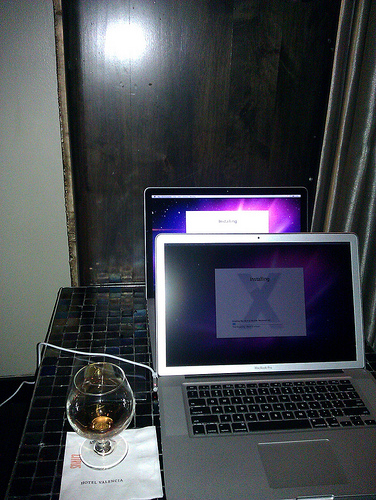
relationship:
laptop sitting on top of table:
[151, 234, 374, 497] [4, 283, 362, 498]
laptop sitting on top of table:
[143, 184, 309, 367] [4, 283, 362, 498]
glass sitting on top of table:
[65, 361, 137, 470] [4, 283, 362, 498]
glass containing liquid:
[65, 361, 137, 470] [67, 377, 136, 436]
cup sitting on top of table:
[65, 359, 137, 475] [4, 283, 362, 498]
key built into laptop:
[191, 423, 206, 435] [151, 234, 374, 497]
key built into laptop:
[188, 404, 213, 414] [151, 234, 374, 497]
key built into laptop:
[210, 386, 222, 397] [151, 234, 374, 497]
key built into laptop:
[190, 406, 212, 415] [151, 234, 374, 497]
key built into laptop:
[234, 388, 247, 396] [151, 234, 374, 497]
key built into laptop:
[233, 386, 247, 394] [151, 234, 374, 497]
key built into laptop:
[278, 395, 290, 403] [151, 234, 374, 497]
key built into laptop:
[278, 394, 291, 402] [151, 234, 374, 497]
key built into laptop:
[296, 400, 310, 410] [151, 234, 374, 497]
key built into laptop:
[295, 400, 310, 410] [151, 234, 374, 497]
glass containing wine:
[65, 361, 137, 470] [67, 375, 132, 437]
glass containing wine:
[65, 361, 137, 470] [68, 379, 134, 435]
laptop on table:
[151, 234, 374, 497] [0, 282, 183, 497]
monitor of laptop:
[164, 241, 357, 365] [151, 234, 374, 497]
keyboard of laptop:
[176, 377, 364, 443] [151, 234, 374, 497]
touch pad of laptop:
[256, 437, 350, 489] [151, 234, 374, 497]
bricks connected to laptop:
[105, 340, 120, 348] [151, 234, 374, 497]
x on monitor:
[233, 269, 304, 335] [164, 241, 357, 365]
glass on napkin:
[65, 361, 137, 470] [65, 429, 158, 498]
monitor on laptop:
[164, 241, 357, 365] [151, 234, 374, 497]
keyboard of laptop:
[179, 380, 376, 437] [151, 234, 374, 497]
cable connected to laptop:
[5, 339, 153, 410] [151, 234, 374, 497]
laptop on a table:
[151, 234, 374, 497] [9, 270, 175, 495]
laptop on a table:
[143, 184, 309, 367] [9, 270, 175, 495]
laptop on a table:
[151, 234, 374, 497] [7, 282, 166, 498]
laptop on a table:
[143, 184, 309, 367] [7, 282, 166, 498]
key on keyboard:
[234, 388, 247, 396] [165, 374, 363, 490]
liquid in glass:
[85, 421, 110, 436] [59, 360, 145, 474]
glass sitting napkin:
[65, 361, 137, 470] [67, 464, 121, 494]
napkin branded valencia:
[65, 475, 147, 495] [76, 477, 125, 484]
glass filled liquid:
[65, 361, 137, 470] [76, 403, 119, 433]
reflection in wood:
[79, 6, 167, 83] [53, 0, 373, 295]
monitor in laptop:
[164, 241, 357, 365] [151, 234, 374, 497]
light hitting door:
[81, 13, 171, 82] [51, 2, 373, 289]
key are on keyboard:
[190, 406, 212, 415] [155, 227, 375, 497]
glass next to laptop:
[65, 361, 137, 470] [151, 234, 374, 497]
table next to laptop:
[9, 270, 175, 495] [151, 234, 374, 497]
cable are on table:
[0, 339, 156, 407] [7, 282, 166, 498]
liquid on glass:
[67, 377, 136, 436] [66, 353, 135, 469]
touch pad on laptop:
[254, 436, 356, 490] [151, 234, 374, 497]